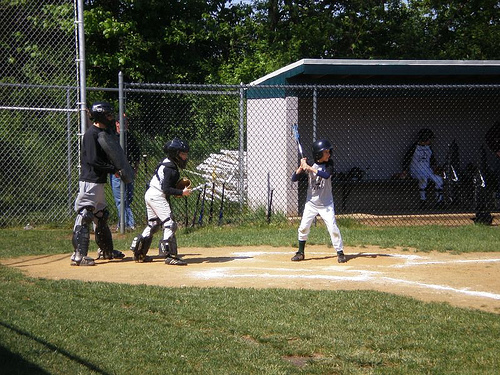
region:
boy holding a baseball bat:
[275, 99, 367, 275]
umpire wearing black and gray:
[55, 90, 131, 276]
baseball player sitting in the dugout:
[354, 114, 461, 219]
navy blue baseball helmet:
[300, 132, 347, 163]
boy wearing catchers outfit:
[132, 130, 199, 272]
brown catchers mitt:
[167, 172, 199, 203]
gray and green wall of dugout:
[223, 51, 313, 231]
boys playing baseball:
[32, 29, 483, 282]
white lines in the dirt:
[204, 237, 434, 311]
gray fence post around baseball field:
[58, 3, 98, 275]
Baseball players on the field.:
[77, 88, 448, 318]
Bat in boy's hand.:
[281, 116, 331, 177]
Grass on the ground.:
[20, 204, 482, 341]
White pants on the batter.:
[265, 181, 380, 281]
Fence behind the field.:
[66, 63, 496, 278]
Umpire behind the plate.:
[62, 85, 146, 280]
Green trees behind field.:
[117, 20, 264, 95]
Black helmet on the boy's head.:
[304, 121, 344, 171]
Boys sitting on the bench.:
[344, 111, 474, 189]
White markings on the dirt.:
[205, 235, 473, 313]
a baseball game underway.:
[0, 38, 475, 318]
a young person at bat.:
[270, 106, 377, 271]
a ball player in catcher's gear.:
[132, 117, 197, 277]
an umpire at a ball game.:
[52, 90, 127, 271]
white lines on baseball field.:
[385, 251, 471, 306]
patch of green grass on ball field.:
[65, 295, 390, 340]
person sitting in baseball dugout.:
[341, 92, 442, 202]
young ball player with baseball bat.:
[270, 105, 355, 261]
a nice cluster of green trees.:
[116, 15, 236, 70]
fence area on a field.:
[20, 12, 95, 92]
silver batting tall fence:
[30, 27, 103, 102]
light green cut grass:
[67, 303, 347, 353]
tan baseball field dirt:
[114, 254, 175, 278]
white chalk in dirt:
[194, 265, 261, 277]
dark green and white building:
[261, 54, 461, 90]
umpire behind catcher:
[67, 97, 136, 276]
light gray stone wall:
[242, 109, 288, 221]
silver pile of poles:
[197, 135, 244, 199]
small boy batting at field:
[284, 134, 357, 260]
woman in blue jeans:
[108, 182, 148, 227]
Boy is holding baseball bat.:
[288, 118, 312, 187]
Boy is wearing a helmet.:
[310, 137, 332, 154]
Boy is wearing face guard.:
[163, 133, 192, 172]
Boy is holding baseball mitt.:
[173, 174, 197, 204]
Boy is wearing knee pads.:
[132, 211, 181, 239]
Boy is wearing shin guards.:
[131, 230, 180, 267]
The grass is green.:
[4, 281, 499, 373]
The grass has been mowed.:
[1, 275, 483, 373]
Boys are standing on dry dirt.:
[26, 96, 426, 301]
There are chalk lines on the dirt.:
[186, 232, 496, 309]